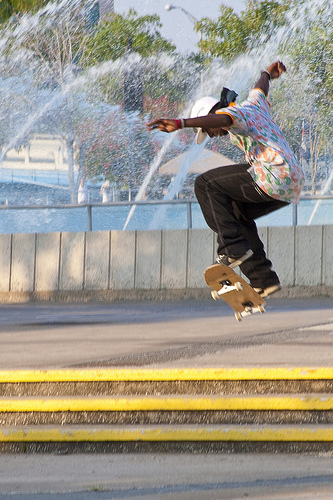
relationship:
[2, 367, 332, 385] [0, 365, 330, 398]
line on step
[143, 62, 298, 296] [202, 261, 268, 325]
person on skateboard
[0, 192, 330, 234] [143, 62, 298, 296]
fence behind person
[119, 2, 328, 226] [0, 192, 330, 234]
spout behind fence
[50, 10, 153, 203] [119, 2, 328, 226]
tree behind spout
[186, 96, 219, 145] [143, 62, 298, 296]
cap on person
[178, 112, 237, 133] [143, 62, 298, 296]
arm on person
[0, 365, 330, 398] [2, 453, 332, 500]
step by ground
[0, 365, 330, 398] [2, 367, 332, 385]
step with a line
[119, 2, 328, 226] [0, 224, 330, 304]
spout behind wall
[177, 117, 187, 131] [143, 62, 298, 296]
band on person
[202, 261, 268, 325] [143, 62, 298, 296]
skateboard under person